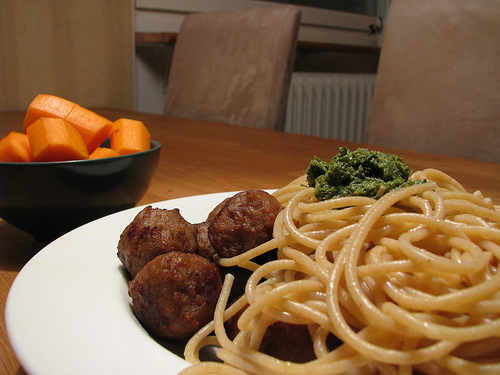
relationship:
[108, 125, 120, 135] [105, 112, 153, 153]
dark spot on carrot slice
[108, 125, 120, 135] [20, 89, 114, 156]
dark spot on carrot slice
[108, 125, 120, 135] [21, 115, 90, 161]
dark spot on carrot slice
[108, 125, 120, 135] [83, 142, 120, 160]
dark spot on carrot slice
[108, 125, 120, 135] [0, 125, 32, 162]
dark spot on carrot slice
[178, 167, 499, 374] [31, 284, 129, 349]
noodles on plate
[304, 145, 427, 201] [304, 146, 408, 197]
green paste on noodles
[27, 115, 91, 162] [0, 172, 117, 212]
carrot slice in bowl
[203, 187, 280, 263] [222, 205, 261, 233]
ball of meat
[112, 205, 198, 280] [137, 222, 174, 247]
ball of meat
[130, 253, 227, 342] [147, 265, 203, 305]
ball of meat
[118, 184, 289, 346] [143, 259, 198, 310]
balls of meat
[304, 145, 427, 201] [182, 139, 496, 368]
green paste on noodles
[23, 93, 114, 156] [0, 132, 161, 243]
carrot slice in bowl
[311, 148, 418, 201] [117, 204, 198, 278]
green paste on ball